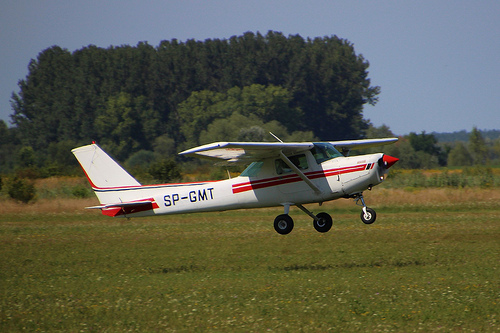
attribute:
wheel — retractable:
[271, 214, 297, 243]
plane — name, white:
[76, 130, 390, 247]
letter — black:
[155, 181, 192, 231]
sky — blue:
[31, 11, 253, 54]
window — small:
[268, 148, 319, 186]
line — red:
[233, 167, 358, 189]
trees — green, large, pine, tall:
[35, 33, 362, 151]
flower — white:
[162, 268, 409, 329]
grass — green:
[29, 197, 428, 320]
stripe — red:
[226, 145, 363, 194]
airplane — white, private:
[76, 105, 391, 240]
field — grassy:
[20, 225, 459, 312]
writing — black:
[163, 183, 244, 208]